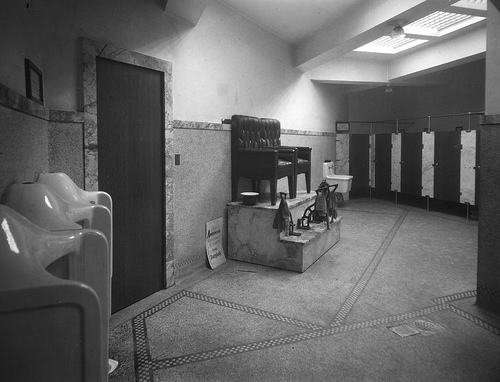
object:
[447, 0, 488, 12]
lights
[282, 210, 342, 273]
step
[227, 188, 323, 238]
step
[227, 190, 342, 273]
stand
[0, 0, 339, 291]
wall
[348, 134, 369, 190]
stall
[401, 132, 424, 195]
stall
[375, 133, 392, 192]
stall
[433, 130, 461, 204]
stall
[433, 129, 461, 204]
door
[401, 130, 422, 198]
door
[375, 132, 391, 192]
door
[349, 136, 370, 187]
door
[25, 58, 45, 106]
frame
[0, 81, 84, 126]
ledge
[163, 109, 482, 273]
station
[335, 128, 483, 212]
row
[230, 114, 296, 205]
cushioned seat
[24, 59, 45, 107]
sign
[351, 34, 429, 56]
lights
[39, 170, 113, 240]
urinals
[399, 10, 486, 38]
lights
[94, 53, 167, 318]
door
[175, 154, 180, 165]
light switch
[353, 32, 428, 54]
exhaust fan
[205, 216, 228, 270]
flyer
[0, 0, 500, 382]
washroom.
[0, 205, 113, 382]
urinals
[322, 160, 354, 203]
sink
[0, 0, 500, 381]
bathroom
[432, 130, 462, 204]
bathroom stalls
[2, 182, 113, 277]
urinals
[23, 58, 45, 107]
certificate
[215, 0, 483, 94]
ceiling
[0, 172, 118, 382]
row